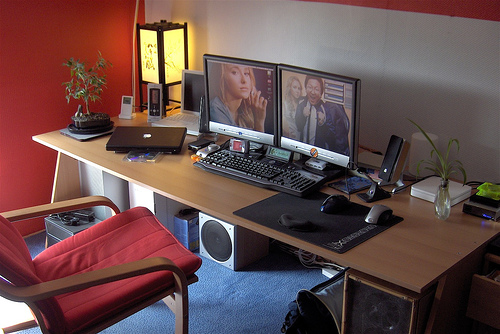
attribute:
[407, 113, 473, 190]
plant — small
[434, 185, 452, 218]
vase — clear, glass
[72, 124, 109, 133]
vase — black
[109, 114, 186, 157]
laptop — apple, black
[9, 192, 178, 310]
chair — red, wooden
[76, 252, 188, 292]
frame — wooden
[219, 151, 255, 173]
keyboard — black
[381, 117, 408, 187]
subwoofer — black, silver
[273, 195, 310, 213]
mouse pad — black, giant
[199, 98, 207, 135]
speaker — black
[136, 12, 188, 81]
lamp — yellow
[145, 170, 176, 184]
table — wooden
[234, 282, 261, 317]
floor — blue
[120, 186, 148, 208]
device — white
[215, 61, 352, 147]
screens — double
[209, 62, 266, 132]
monitor — double